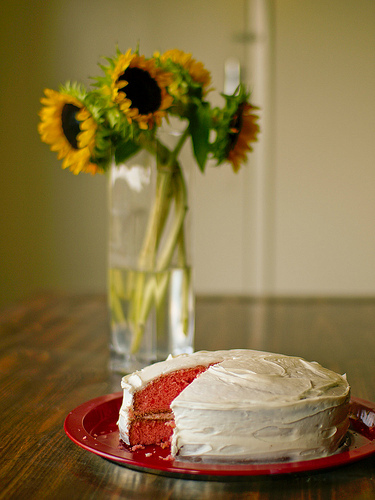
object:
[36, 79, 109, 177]
sunflower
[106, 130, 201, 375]
vase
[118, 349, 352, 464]
cake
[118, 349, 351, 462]
icing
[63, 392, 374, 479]
plate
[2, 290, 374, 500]
table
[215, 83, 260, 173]
sunflowers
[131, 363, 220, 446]
interior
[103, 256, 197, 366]
water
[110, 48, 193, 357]
sunflower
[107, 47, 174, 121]
head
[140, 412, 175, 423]
frosting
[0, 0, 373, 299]
wall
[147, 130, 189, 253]
stem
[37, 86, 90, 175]
petals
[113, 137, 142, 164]
leaves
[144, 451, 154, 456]
crumbs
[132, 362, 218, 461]
missing piece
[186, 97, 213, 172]
leaf